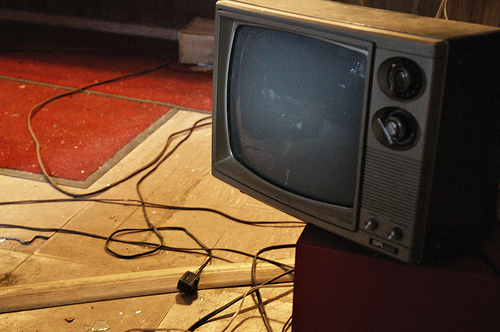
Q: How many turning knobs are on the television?
A: Four.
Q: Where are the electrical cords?
A: On the floor.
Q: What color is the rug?
A: Red with a brown border.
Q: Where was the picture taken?
A: Inside of a room.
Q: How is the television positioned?
A: Towards the edge.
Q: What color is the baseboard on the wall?
A: White.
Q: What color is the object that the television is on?
A: Maroon.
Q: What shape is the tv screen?
A: A square.